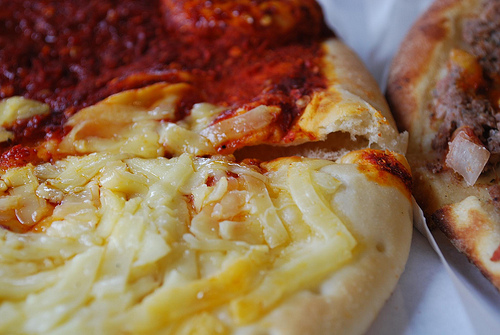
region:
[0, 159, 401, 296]
something very cheesy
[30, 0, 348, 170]
something with nice red sauce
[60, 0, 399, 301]
pizza crust looking good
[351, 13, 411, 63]
a white sheet where the pizza is laying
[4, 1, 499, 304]
two pizzas next to each other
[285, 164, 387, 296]
some cheese and onions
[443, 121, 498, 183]
onions and meat on the pizza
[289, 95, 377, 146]
the yummy pizza crust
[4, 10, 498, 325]
a cool scene of food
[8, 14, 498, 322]
very good looking food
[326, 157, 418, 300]
Bright white toasted bread crust.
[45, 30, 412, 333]
Melt yellow cheese.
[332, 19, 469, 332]
A white cloth under the food.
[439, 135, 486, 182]
A slice of onion.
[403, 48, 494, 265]
The bread crust is toasted brown.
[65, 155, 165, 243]
A close up of some cheese.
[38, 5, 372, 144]
The background is unfocused.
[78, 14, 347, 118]
Red sauce.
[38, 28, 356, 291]
This food is red and yellow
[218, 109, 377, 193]
This bread is breaking off.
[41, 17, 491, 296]
A pizza next to another pizza.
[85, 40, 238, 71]
The sauce is red.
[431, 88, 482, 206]
Onions on the pizza.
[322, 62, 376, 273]
The crust is light yellow.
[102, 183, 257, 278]
Cheese on the pizza.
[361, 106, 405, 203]
Part of the crust is burnt.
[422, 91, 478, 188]
Pieces of onion on the pizza.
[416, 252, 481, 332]
The cloth is white.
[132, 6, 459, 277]
One pizza is bigger than the other.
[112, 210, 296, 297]
Some of the cheese is melted.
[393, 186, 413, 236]
edge of a pizza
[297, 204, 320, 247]
yellow part of a pizza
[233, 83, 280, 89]
red section on a pizza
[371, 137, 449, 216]
edge of two pizzas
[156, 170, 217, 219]
part of pizza vegetable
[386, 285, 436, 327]
section of a table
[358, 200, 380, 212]
outer part of a pizza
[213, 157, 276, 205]
inner part of a pizza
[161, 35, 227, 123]
sauce on a pizza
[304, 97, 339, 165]
portion of a pizza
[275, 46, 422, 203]
soft and doughy pizza crust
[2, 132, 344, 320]
pizza with sauce and cheese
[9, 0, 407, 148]
bright red pizza sauce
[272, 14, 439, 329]
white pizza crust below toppings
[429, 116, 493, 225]
small pieces of onion on a pizza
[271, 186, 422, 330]
small holes puncture the pizza crust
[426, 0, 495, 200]
onions and hamburger on a pizza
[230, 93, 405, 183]
small air pockets in pizza crust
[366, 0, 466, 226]
crispy edges of pizza crust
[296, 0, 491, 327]
the color white shows from beneath the pizza